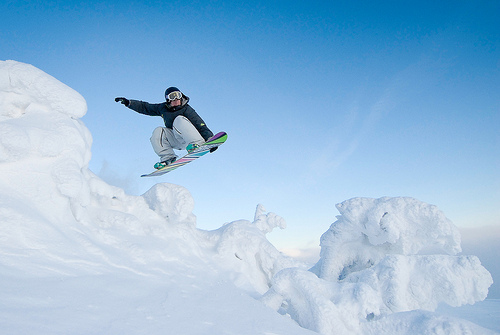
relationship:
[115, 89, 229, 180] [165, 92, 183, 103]
snowboarder has goggles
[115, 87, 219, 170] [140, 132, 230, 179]
man on snowboard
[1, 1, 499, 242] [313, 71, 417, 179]
sky has clouds